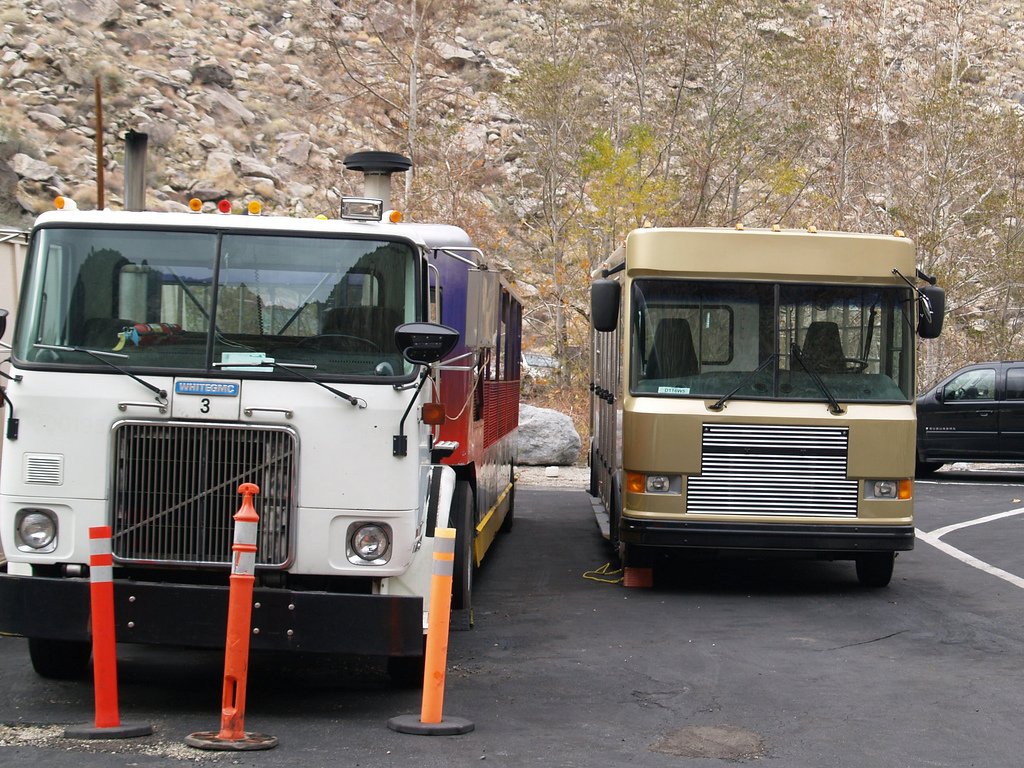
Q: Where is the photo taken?
A: In the mountains.